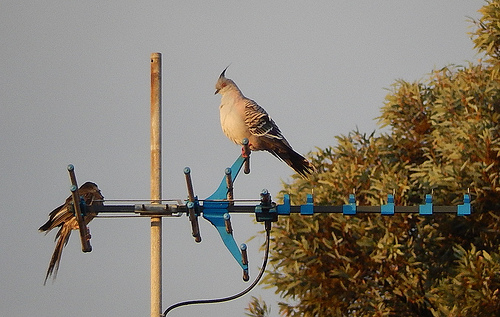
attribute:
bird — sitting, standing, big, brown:
[215, 66, 319, 183]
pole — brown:
[150, 50, 163, 316]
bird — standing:
[39, 181, 104, 284]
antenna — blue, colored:
[69, 138, 474, 282]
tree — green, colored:
[242, 2, 499, 317]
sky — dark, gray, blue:
[1, 1, 490, 316]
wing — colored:
[245, 98, 282, 140]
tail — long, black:
[273, 128, 319, 181]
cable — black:
[163, 222, 272, 316]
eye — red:
[222, 82, 226, 87]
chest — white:
[221, 95, 240, 129]